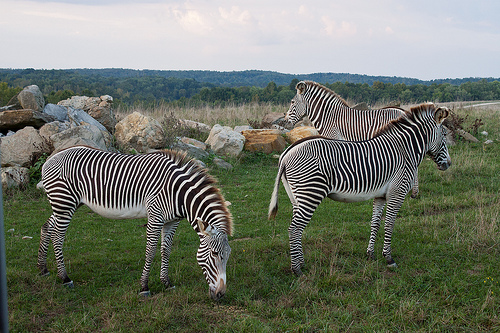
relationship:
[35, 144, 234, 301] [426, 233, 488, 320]
zebra standing on field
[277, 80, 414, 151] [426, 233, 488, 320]
zebras standing on field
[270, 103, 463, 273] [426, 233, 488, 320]
zebras standing on field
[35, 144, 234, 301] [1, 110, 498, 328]
zebra grazing on grass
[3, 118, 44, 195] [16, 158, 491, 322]
rock in field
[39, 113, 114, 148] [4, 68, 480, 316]
large rock in field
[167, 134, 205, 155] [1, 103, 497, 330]
rock in field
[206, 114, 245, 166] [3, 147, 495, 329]
rock in field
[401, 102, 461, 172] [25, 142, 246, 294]
head of zebra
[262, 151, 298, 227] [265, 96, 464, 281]
tail of zebra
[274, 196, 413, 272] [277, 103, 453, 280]
legs of zebra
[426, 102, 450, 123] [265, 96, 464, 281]
ears of zebra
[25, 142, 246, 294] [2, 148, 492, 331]
zebra eating grass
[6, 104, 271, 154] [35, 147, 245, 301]
rocks behind zerbas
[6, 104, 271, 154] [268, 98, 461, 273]
rocks behind zerbas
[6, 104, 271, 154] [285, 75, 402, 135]
rocks behind zerbas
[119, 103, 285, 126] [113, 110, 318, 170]
brown grass behind rock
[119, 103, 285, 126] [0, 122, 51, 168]
brown grass behind large rock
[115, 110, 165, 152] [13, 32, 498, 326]
rock in field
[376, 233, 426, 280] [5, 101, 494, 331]
grass on ground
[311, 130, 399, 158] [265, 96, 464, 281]
back of zebra